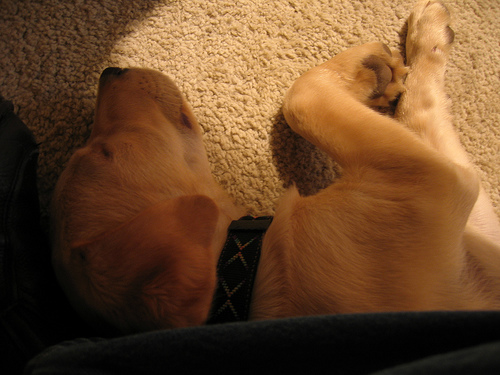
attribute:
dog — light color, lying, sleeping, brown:
[44, 0, 493, 301]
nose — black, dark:
[51, 65, 231, 328]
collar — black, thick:
[201, 207, 271, 333]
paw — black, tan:
[357, 0, 464, 106]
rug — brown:
[3, 4, 499, 216]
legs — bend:
[294, 4, 490, 199]